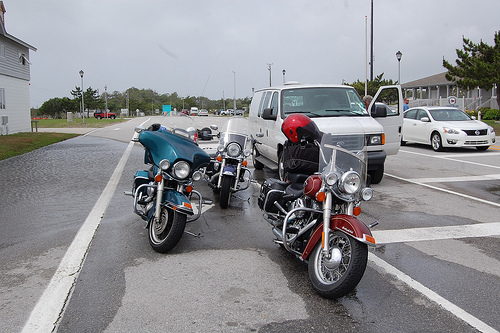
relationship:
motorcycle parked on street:
[120, 124, 215, 257] [4, 114, 498, 329]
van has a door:
[246, 82, 405, 188] [368, 84, 407, 160]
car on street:
[397, 104, 498, 153] [4, 114, 498, 329]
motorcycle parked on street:
[259, 135, 376, 301] [4, 114, 498, 329]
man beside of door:
[358, 94, 386, 115] [368, 84, 407, 160]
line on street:
[17, 109, 158, 332] [4, 114, 498, 329]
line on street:
[362, 250, 494, 333] [4, 114, 498, 329]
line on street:
[383, 172, 499, 210] [4, 114, 498, 329]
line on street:
[398, 146, 498, 170] [4, 114, 498, 329]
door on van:
[368, 84, 407, 160] [246, 82, 405, 188]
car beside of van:
[397, 104, 498, 153] [246, 82, 405, 188]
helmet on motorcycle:
[280, 113, 324, 146] [259, 135, 376, 301]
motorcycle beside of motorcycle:
[208, 112, 260, 212] [120, 124, 215, 257]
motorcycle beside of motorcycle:
[208, 112, 260, 212] [259, 135, 376, 301]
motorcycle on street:
[259, 135, 376, 301] [4, 114, 498, 329]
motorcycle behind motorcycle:
[208, 112, 260, 212] [259, 135, 376, 301]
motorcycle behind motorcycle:
[120, 124, 215, 257] [208, 112, 260, 212]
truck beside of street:
[93, 107, 119, 124] [4, 114, 498, 329]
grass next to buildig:
[2, 132, 78, 163] [1, 2, 41, 137]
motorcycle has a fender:
[259, 135, 376, 301] [297, 213, 380, 263]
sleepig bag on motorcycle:
[280, 140, 319, 176] [259, 135, 376, 301]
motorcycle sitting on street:
[259, 135, 376, 301] [4, 114, 498, 329]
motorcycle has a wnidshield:
[259, 135, 376, 301] [320, 123, 370, 206]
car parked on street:
[397, 104, 498, 153] [4, 114, 498, 329]